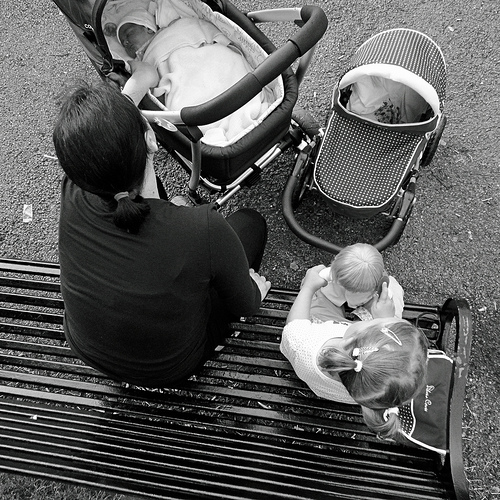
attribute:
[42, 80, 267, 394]
woman — seated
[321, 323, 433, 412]
hair — pulled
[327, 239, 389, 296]
hair — blonde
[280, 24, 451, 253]
stroller — for a doll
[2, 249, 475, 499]
bench — black, metal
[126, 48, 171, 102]
hand — woman's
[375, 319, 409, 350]
barrette — white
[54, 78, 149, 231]
hair — dark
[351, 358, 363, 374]
ponytail holder — white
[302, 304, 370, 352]
shirt — white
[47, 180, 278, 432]
shirt — black, long sleeve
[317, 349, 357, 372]
ponytail — blond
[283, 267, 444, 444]
young girl — sitting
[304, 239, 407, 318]
doll — baby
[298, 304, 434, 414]
girl — young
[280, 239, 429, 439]
girl — seated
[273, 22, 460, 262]
carriage — white and black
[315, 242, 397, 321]
doll — baby